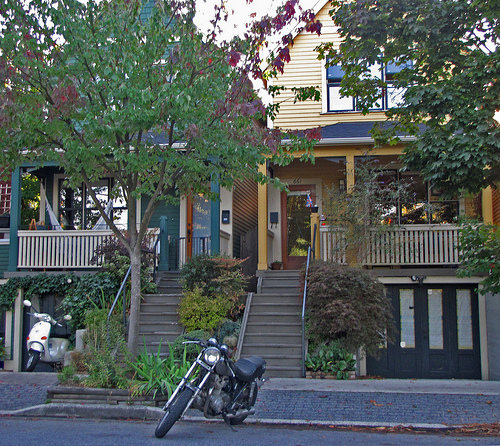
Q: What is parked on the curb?
A: Motorbike.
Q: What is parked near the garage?
A: Moped.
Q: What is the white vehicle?
A: Moped.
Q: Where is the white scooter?
A: In front of the garage.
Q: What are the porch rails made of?
A: Wood.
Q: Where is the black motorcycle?
A: Parked on the curb.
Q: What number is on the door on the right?
A: 661.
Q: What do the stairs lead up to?
A: Front doors.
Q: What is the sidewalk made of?
A: Bricks.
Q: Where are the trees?
A: In front of the house.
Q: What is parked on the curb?
A: A black motorcycle.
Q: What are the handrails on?
A: The front stairs.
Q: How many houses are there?
A: Two.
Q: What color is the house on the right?
A: Yellow.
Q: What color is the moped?
A: White.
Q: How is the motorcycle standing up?
A: The kick stand.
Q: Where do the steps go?
A: To the houses.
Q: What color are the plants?
A: Green.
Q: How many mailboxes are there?
A: Two.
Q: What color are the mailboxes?
A: Black.